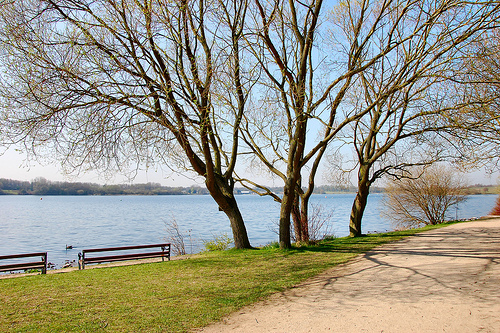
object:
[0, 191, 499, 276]
water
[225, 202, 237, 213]
bark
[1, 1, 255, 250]
tree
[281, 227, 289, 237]
bark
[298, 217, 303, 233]
bark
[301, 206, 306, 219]
bark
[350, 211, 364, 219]
bark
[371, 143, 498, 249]
tree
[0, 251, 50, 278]
bench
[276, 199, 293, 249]
trunk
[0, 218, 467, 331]
grass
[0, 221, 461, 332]
grassy area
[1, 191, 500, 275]
lake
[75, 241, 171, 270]
bench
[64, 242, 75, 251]
bird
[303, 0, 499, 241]
tree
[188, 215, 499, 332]
pavement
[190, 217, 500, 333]
sand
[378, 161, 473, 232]
bush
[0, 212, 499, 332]
floor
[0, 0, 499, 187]
sky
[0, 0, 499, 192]
cloud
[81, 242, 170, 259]
gape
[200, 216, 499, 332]
dirt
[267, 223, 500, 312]
shadow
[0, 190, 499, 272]
waves